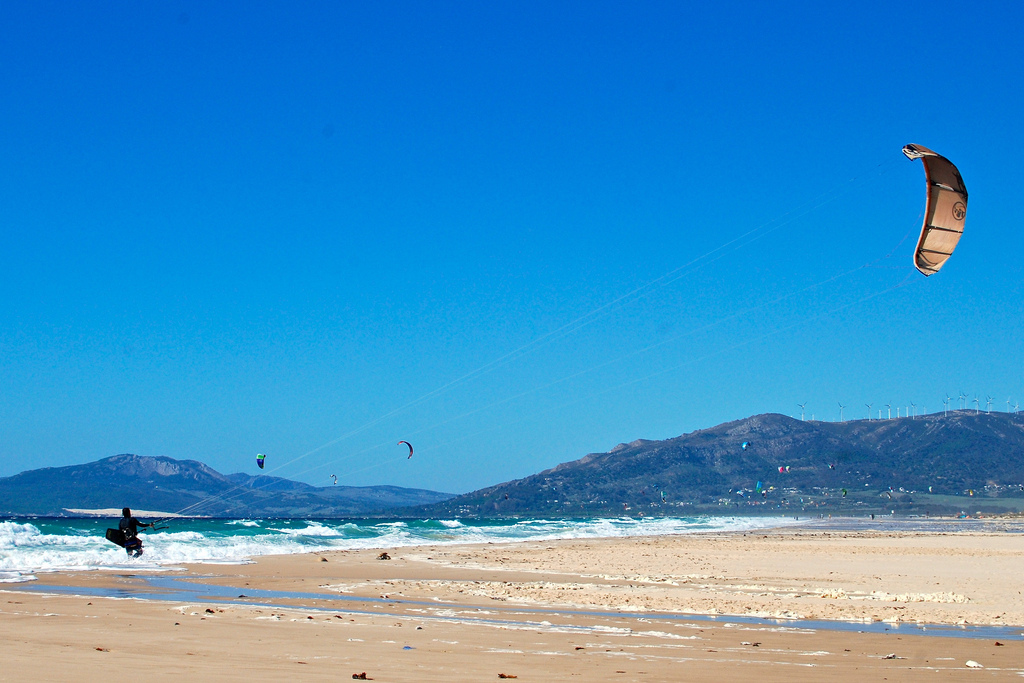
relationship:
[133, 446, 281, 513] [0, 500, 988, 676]
mountain by beach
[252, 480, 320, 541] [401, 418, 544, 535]
leaves on tree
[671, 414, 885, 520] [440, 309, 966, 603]
grass on mountain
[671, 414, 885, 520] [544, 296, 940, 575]
grass on mountain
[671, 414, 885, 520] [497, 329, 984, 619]
grass on mountain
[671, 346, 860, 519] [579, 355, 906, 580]
grass on mountain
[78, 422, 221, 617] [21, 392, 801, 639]
person on beach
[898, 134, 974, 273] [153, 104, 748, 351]
kite in sky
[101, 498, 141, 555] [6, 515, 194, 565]
surfer walking in ocean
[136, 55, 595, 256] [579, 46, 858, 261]
sky with no clouds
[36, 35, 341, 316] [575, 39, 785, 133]
sky with no clouds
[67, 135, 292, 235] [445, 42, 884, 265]
sky with no clouds